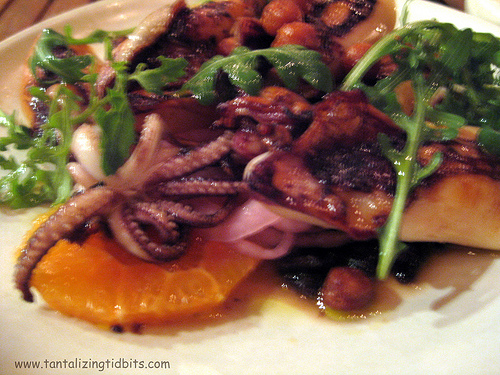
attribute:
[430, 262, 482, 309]
shadow — food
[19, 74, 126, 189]
vegetable — green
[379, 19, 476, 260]
vegetable — green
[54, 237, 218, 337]
orange — glistening, slice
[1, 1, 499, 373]
plate — white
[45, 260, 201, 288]
hot dogs — bunch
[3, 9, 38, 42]
table — dark brown, portion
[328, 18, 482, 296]
vegetable — green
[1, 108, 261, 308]
calamari — portion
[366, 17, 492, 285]
green stem — thin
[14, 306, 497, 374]
plate — section, white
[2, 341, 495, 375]
background — tan